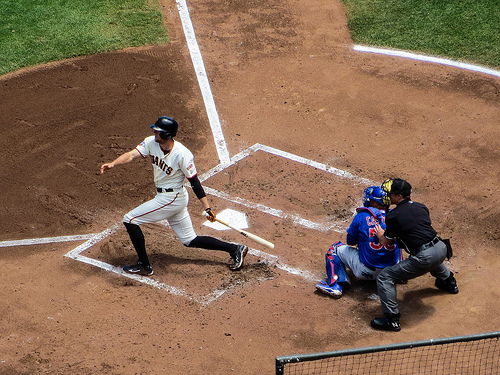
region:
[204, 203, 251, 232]
A white home plate.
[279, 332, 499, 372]
A black fence.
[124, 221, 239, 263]
Long black socks.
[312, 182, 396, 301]
A catcher.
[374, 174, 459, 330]
An umpire.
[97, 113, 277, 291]
A man who is holding a baseball bat.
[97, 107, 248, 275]
A baseball player.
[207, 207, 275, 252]
A white baseball bat.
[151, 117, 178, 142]
A black baseball helmet.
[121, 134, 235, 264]
A white and black baseball uniform.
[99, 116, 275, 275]
a baseball player swinging at ball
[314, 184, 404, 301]
a catcher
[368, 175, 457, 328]
a squating umpire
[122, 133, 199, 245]
a whtie baseball uniform with black and orange trim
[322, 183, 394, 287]
a blue and red baseball uniform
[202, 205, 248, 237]
homeplate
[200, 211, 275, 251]
a wooden baseball bat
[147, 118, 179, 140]
hard protective helmet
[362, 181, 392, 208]
a hard catchers mask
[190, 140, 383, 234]
right-sided batters box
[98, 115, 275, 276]
a baseball player about to drop his bat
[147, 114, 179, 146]
a man wearing a black hard hat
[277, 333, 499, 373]
a metal fence on a baseball field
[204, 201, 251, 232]
a white home plate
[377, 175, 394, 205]
an umpire wearing a yellow mask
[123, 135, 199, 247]
a baseball player wearing a white uniform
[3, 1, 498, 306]
white lines on a baseball field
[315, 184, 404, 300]
a catcher wearing a blue and red uniform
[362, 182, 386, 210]
a blue catcher's mask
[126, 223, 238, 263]
a baseball player wearing long knee socks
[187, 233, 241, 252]
long black sock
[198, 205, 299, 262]
white baseball bat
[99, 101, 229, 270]
bseball layer in white and black uniform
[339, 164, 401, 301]
catcher crouched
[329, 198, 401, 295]
blue andred uniform of catcher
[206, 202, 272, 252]
white home plate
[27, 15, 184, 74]
green grass on the field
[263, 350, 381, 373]
netted meta fence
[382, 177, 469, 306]
guy in black and grey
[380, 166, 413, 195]
black baseball cap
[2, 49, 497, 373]
dirt of baseball field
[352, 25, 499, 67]
green grass of field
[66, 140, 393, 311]
white lines designating batter's box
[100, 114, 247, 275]
baseball player with twisted body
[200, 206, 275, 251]
gloved hand on baseball bat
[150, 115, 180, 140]
black helmet on head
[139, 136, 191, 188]
shirt with team name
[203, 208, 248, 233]
white surface of home plate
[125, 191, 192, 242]
pant legs with stripe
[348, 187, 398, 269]
catcher in blue shirt